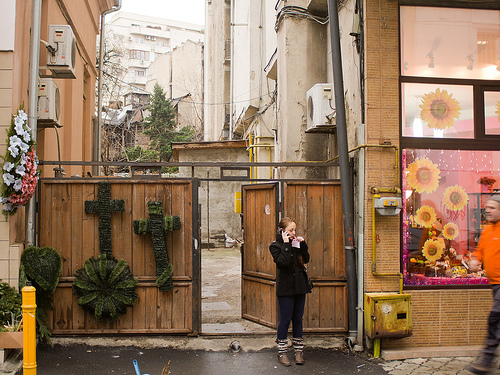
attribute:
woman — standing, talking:
[269, 217, 314, 366]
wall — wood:
[34, 178, 196, 336]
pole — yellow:
[20, 285, 40, 373]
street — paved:
[0, 348, 499, 374]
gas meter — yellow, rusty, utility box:
[365, 291, 414, 338]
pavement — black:
[25, 346, 387, 374]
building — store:
[232, 2, 500, 362]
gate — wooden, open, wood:
[240, 183, 280, 331]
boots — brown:
[275, 339, 306, 366]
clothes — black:
[269, 235, 312, 337]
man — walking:
[465, 195, 499, 374]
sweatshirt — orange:
[473, 222, 499, 283]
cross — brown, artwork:
[83, 181, 126, 256]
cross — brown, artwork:
[135, 198, 179, 293]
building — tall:
[99, 10, 209, 122]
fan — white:
[305, 85, 341, 134]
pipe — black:
[325, 0, 357, 347]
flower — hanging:
[0, 106, 40, 218]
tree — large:
[129, 82, 201, 175]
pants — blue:
[276, 293, 307, 338]